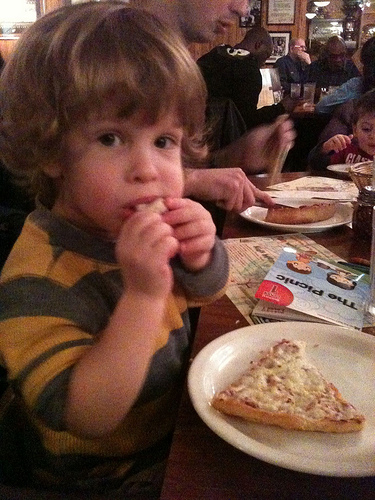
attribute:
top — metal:
[352, 179, 373, 207]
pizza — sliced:
[205, 336, 367, 440]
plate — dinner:
[182, 315, 373, 480]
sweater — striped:
[4, 195, 231, 480]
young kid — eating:
[4, 60, 217, 488]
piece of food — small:
[128, 187, 168, 217]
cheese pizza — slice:
[219, 321, 360, 462]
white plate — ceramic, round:
[183, 301, 373, 475]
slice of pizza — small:
[222, 329, 358, 435]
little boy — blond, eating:
[7, 50, 231, 485]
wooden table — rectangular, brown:
[169, 147, 373, 476]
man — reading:
[139, 2, 353, 251]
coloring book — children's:
[255, 234, 371, 344]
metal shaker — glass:
[347, 183, 374, 265]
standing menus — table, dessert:
[207, 230, 374, 343]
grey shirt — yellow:
[8, 206, 190, 478]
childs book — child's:
[252, 230, 374, 342]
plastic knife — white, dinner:
[268, 194, 308, 212]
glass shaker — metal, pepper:
[342, 178, 371, 262]